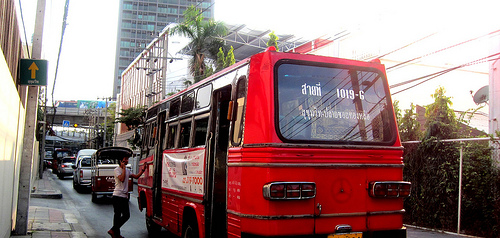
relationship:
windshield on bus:
[273, 57, 402, 147] [115, 51, 425, 207]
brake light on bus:
[267, 169, 360, 225] [123, 44, 412, 232]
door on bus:
[202, 90, 237, 234] [100, 52, 445, 236]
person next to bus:
[98, 156, 144, 232] [163, 50, 407, 222]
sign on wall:
[15, 57, 49, 87] [13, 30, 81, 228]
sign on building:
[15, 57, 49, 87] [0, 6, 90, 235]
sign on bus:
[157, 150, 220, 202] [123, 87, 393, 236]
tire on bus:
[181, 209, 196, 236] [123, 44, 412, 232]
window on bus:
[192, 115, 208, 145] [123, 44, 412, 232]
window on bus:
[132, 51, 424, 236] [146, 48, 454, 223]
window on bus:
[179, 122, 191, 146] [123, 44, 412, 232]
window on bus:
[163, 117, 178, 151] [123, 44, 412, 232]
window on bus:
[165, 94, 182, 120] [123, 44, 412, 232]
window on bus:
[179, 89, 196, 114] [123, 44, 412, 232]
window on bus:
[192, 80, 216, 110] [123, 44, 412, 232]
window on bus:
[272, 56, 397, 143] [123, 44, 412, 232]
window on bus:
[149, 122, 157, 143] [123, 44, 412, 232]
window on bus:
[141, 122, 147, 144] [123, 44, 412, 232]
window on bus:
[165, 94, 182, 120] [106, 57, 411, 227]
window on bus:
[140, 107, 162, 117] [93, 62, 453, 232]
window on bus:
[272, 56, 397, 143] [132, 47, 426, 236]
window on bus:
[226, 71, 250, 151] [123, 44, 412, 232]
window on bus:
[147, 127, 162, 147] [139, 53, 403, 235]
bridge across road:
[44, 103, 112, 134] [50, 138, 430, 235]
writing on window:
[293, 75, 374, 122] [272, 56, 397, 143]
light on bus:
[264, 178, 321, 200] [123, 44, 412, 232]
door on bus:
[202, 90, 237, 234] [67, 40, 383, 235]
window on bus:
[174, 115, 192, 149] [123, 44, 412, 232]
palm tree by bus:
[172, 2, 232, 85] [123, 44, 412, 232]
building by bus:
[106, 22, 240, 102] [139, 68, 423, 234]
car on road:
[88, 146, 132, 203] [45, 132, 186, 237]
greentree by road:
[401, 129, 499, 237] [50, 138, 430, 235]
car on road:
[88, 146, 132, 203] [55, 158, 155, 236]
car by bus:
[88, 146, 132, 203] [123, 44, 412, 232]